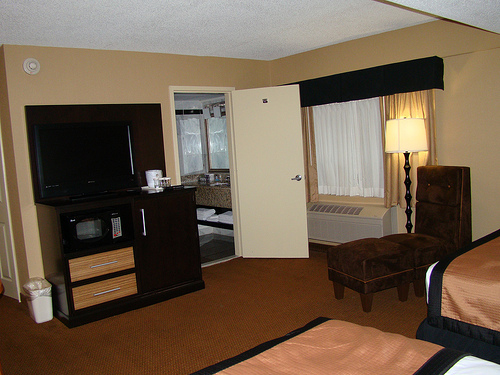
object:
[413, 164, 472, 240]
backrest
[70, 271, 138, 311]
drawer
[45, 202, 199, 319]
cabinet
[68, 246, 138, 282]
drawer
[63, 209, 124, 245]
microwave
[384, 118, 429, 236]
lamp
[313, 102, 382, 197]
curtain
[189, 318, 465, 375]
throw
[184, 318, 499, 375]
bed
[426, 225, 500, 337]
throw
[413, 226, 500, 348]
bed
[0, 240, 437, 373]
carpet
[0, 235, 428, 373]
floor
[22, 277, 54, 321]
bag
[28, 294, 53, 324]
trash-can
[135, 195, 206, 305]
door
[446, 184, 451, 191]
button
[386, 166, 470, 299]
chair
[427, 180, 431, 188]
button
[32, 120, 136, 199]
tv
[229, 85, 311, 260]
door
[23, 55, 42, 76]
smoke-detector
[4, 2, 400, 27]
ceiling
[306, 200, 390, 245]
ac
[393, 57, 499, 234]
wall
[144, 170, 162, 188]
bucket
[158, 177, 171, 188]
glasses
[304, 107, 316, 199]
drapes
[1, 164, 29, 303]
door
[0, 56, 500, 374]
room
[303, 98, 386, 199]
window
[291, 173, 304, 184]
handle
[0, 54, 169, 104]
wall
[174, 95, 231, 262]
bathroom